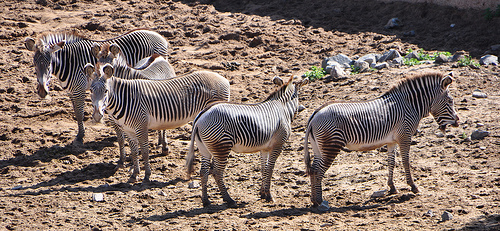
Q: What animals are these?
A: Zebras.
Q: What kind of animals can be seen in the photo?
A: Zebras.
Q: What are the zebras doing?
A: Standing.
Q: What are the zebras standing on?
A: Dirt.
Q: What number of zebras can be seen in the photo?
A: Five.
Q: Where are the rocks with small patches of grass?
A: Behind the zebras.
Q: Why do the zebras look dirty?
A: Because they are walking in a muddy field.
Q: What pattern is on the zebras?
A: White and black stripes.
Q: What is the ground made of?
A: Dirt.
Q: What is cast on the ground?
A: Shadows.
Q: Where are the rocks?
A: On the ground.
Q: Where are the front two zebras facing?
A: The right.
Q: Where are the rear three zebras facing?
A: The left.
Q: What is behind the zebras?
A: Rocks.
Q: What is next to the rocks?
A: Grass.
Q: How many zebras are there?
A: Five.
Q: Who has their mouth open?
A: Biggest zebra.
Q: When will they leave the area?
A: To look for food.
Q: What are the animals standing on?
A: Dirt.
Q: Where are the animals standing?
A: In the sunlight.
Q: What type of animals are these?
A: Zebras.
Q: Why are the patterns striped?
A: It's her unique look.